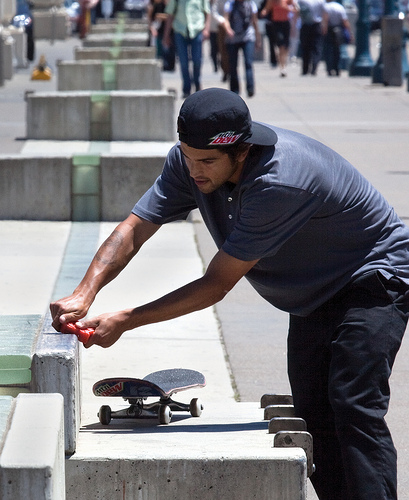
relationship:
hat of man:
[176, 87, 279, 150] [47, 86, 407, 499]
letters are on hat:
[208, 130, 243, 146] [176, 87, 279, 150]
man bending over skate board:
[47, 86, 407, 499] [92, 368, 208, 426]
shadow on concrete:
[84, 419, 276, 439] [67, 399, 307, 498]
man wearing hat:
[47, 86, 407, 499] [176, 87, 279, 150]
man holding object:
[47, 86, 407, 499] [58, 322, 96, 343]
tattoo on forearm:
[93, 227, 128, 268] [73, 223, 143, 301]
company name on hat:
[208, 130, 243, 146] [176, 87, 279, 150]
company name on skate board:
[94, 380, 126, 401] [92, 368, 208, 426]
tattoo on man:
[93, 227, 128, 268] [47, 86, 407, 499]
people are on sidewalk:
[142, 2, 351, 100] [165, 44, 408, 497]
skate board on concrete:
[92, 368, 208, 426] [67, 399, 307, 498]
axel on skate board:
[110, 404, 159, 419] [92, 368, 208, 426]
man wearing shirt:
[47, 86, 407, 499] [129, 121, 408, 318]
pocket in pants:
[370, 269, 399, 303] [285, 268, 408, 500]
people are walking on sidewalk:
[142, 2, 351, 100] [165, 44, 408, 497]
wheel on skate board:
[190, 398, 205, 417] [92, 368, 208, 426]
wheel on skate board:
[157, 404, 174, 425] [92, 368, 208, 426]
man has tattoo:
[47, 86, 407, 499] [93, 227, 128, 268]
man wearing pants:
[47, 86, 407, 499] [285, 268, 408, 500]